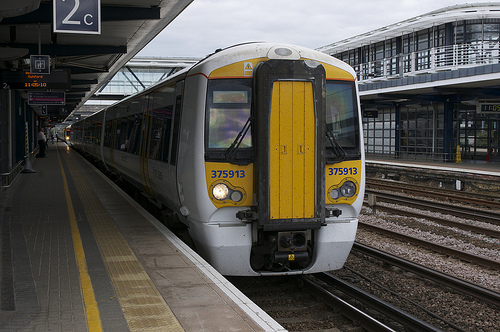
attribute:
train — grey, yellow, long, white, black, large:
[61, 37, 369, 289]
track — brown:
[282, 201, 499, 327]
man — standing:
[35, 123, 49, 157]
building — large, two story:
[351, 2, 499, 162]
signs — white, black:
[51, 2, 104, 37]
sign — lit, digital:
[17, 71, 49, 90]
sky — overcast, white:
[191, 3, 373, 39]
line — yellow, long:
[50, 142, 107, 332]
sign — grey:
[27, 53, 55, 75]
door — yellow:
[265, 77, 321, 222]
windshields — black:
[208, 79, 358, 161]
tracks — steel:
[359, 207, 496, 328]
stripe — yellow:
[66, 147, 184, 331]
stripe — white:
[163, 240, 296, 331]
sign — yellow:
[243, 60, 255, 71]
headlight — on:
[211, 182, 244, 205]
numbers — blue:
[210, 165, 249, 180]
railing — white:
[366, 41, 495, 74]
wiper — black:
[226, 119, 254, 158]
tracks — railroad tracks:
[367, 178, 483, 327]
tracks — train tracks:
[379, 176, 481, 328]